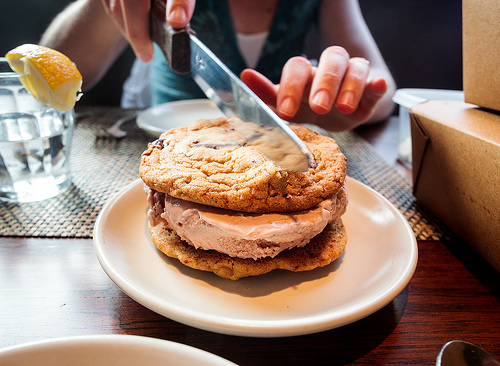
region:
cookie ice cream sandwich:
[139, 117, 348, 282]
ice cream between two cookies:
[155, 207, 345, 254]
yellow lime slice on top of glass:
[5, 42, 83, 109]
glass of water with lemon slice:
[0, 46, 82, 202]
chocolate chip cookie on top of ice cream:
[138, 117, 345, 211]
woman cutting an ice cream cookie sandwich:
[37, 0, 397, 337]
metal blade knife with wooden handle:
[151, 0, 316, 170]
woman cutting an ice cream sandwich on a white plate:
[37, 0, 397, 280]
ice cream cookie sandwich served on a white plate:
[92, 115, 421, 337]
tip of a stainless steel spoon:
[435, 337, 499, 364]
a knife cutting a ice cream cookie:
[161, 33, 326, 205]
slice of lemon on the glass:
[9, 36, 91, 106]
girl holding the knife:
[105, 8, 243, 95]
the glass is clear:
[2, 108, 74, 204]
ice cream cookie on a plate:
[148, 132, 373, 341]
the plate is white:
[114, 259, 424, 337]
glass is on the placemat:
[15, 151, 120, 297]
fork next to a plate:
[84, 109, 141, 150]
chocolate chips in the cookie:
[131, 129, 255, 152]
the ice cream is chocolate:
[170, 209, 352, 255]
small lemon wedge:
[3, 40, 85, 113]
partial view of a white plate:
[0, 327, 242, 362]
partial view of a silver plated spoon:
[431, 337, 496, 362]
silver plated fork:
[89, 105, 144, 141]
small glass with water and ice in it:
[0, 55, 79, 206]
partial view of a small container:
[391, 85, 468, 171]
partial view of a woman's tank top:
[235, 31, 269, 71]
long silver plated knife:
[186, 32, 316, 174]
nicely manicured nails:
[276, 87, 357, 118]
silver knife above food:
[166, 45, 287, 153]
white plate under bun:
[176, 274, 221, 310]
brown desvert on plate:
[163, 130, 331, 274]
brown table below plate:
[411, 265, 476, 320]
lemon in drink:
[8, 46, 103, 118]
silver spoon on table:
[440, 312, 497, 364]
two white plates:
[121, 270, 204, 365]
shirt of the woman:
[198, 6, 315, 64]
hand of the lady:
[255, 40, 380, 155]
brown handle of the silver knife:
[143, 15, 184, 72]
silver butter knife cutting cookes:
[190, 44, 319, 183]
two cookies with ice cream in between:
[137, 97, 372, 285]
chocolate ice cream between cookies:
[153, 187, 351, 260]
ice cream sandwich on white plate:
[130, 113, 375, 289]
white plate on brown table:
[95, 167, 423, 339]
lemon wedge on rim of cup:
[0, 40, 100, 122]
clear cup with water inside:
[1, 62, 94, 212]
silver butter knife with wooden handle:
[140, 4, 331, 196]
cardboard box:
[392, 89, 497, 270]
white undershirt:
[175, 0, 334, 105]